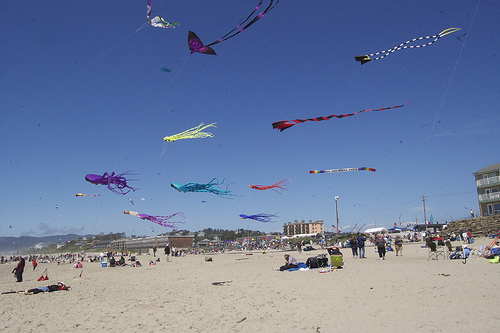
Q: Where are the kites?
A: In the sky.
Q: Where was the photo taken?
A: Beach.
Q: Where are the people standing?
A: On sand.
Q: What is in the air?
A: Kites.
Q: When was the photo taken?
A: During the daytime.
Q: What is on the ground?
A: Sand.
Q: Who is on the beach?
A: People.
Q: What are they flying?
A: Kites.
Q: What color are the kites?
A: Multiple colors.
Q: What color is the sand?
A: Tan.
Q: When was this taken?
A: A windy day.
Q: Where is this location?
A: A sandy beach.